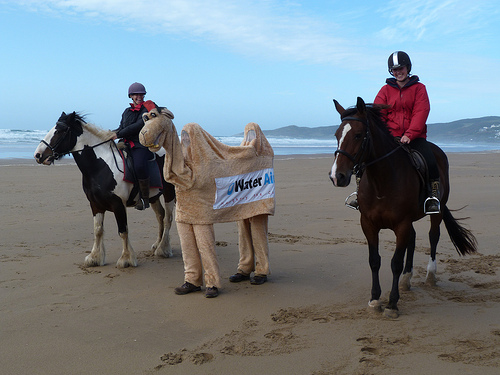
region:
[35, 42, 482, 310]
people riding horses on a beach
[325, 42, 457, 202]
girl in red jacket riding horse on beach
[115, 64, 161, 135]
girl riding horse on beach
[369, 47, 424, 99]
woman in red jacket is laughing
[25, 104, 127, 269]
person riding paint horse on beach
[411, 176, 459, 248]
person using stirrups on saddle when riding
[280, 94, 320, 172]
mountains in the distance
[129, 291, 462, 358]
foot prints on the sand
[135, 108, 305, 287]
two people disguised as a camel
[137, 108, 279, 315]
two people wearing a tan camel costume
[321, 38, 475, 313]
a person riding a horse.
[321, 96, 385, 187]
the head of a brown and white horse.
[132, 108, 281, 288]
Two people disguised as an animal.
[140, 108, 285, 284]
Some people dressed as a brown camel.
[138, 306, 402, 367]
prints in the beach sand.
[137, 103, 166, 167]
a fake camel head.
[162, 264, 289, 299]
Two pairs of dark shoes.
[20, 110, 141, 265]
a beautiful brown and white horse.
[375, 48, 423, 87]
a person wearing a helmet.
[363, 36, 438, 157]
a person wearing a red jacket.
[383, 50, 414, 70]
person wearing dark helmet with a white stripe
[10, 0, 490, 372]
people and animals on the beach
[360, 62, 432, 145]
woman wearing a red jacket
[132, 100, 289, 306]
two people wearing a camel costume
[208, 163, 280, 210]
white, black, and blue sign on fake camel's side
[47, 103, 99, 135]
hairs on horse's mane blowing in the wind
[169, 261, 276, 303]
people in camel costume are wearing dark shoes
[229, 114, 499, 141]
hills in the distance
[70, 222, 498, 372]
sand around group has been disturbed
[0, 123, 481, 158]
ocean in the distance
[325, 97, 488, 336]
a dark brown horse with a rider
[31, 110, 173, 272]
a black and white horse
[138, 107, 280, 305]
two people dressed as a camel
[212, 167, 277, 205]
an advertisement on the side of the fake camel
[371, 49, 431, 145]
a horseback rider in a red jacket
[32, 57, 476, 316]
two horses and a fake camel on a beach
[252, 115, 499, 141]
hills behind the riders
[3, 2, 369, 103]
blue sky with light clouds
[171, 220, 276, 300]
the legs of two people dressed as a camel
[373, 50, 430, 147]
woman wearing a riding helmet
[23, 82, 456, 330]
Two horse are seen.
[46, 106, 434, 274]
Horses are brown and white color.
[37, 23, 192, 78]
Sky is blue color.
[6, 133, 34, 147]
Water is blue color.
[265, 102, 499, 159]
Foot hill is seen behind the water.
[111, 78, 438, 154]
Two people are sitting in the horse.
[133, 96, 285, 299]
Camel doll is standing in sand.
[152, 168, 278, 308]
Two people make the camel doll.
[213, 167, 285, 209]
Advertisement is white color.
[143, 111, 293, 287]
Camel doll is brown color.